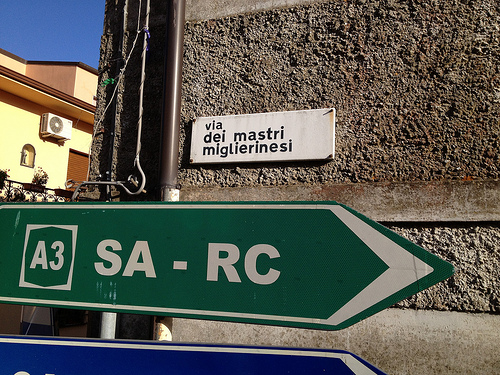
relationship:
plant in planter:
[33, 167, 52, 190] [19, 180, 73, 193]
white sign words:
[192, 105, 343, 164] [184, 114, 310, 160]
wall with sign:
[74, 6, 497, 374] [0, 173, 451, 326]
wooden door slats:
[62, 148, 99, 190] [60, 151, 89, 186]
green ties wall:
[100, 74, 123, 95] [74, 6, 497, 374]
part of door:
[62, 148, 99, 190] [73, 149, 107, 188]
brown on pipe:
[162, 0, 186, 184] [143, 9, 194, 174]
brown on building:
[59, 9, 137, 174] [0, 55, 102, 167]